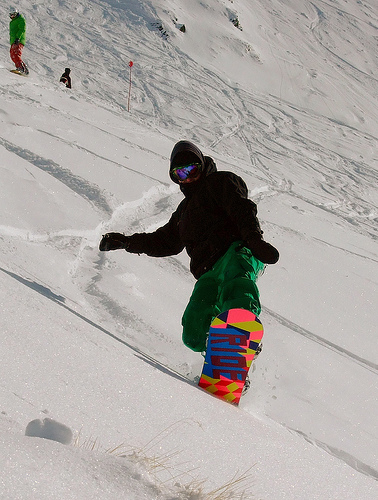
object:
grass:
[81, 414, 266, 498]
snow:
[18, 320, 141, 392]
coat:
[9, 17, 24, 45]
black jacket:
[128, 182, 264, 271]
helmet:
[6, 5, 17, 15]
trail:
[58, 183, 185, 377]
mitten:
[254, 240, 279, 264]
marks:
[39, 50, 345, 210]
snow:
[0, 3, 363, 222]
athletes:
[133, 146, 266, 310]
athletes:
[2, 1, 30, 88]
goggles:
[170, 162, 204, 181]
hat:
[167, 137, 205, 175]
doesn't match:
[2, 2, 376, 495]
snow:
[272, 121, 351, 275]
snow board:
[195, 306, 261, 422]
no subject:
[279, 25, 376, 64]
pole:
[115, 54, 144, 110]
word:
[209, 331, 247, 381]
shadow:
[1, 269, 199, 384]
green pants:
[181, 239, 267, 351]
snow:
[2, 1, 376, 497]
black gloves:
[97, 228, 136, 255]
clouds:
[289, 150, 342, 211]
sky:
[314, 473, 342, 491]